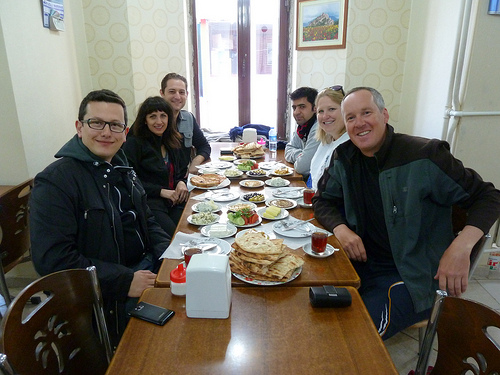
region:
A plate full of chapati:
[226, 219, 300, 283]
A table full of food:
[195, 123, 307, 302]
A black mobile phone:
[126, 301, 171, 326]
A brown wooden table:
[163, 329, 345, 368]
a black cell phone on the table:
[128, 300, 174, 327]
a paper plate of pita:
[229, 228, 301, 288]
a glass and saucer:
[301, 225, 336, 257]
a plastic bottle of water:
[268, 124, 279, 156]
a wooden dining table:
[125, 325, 393, 373]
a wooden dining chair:
[1, 263, 110, 370]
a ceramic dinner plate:
[272, 217, 314, 241]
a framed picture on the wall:
[295, 0, 350, 49]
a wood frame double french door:
[187, 1, 289, 138]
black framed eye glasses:
[80, 116, 130, 133]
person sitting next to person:
[25, 91, 176, 348]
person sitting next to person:
[309, 86, 496, 337]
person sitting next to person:
[122, 95, 194, 239]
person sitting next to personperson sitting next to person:
[159, 72, 210, 182]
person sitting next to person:
[279, 85, 331, 170]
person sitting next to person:
[310, 84, 351, 192]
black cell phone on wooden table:
[128, 301, 178, 333]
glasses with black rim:
[78, 114, 128, 135]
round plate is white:
[198, 222, 236, 239]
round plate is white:
[189, 201, 220, 215]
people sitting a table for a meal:
[4, 45, 498, 368]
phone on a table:
[129, 289, 181, 341]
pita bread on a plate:
[228, 222, 311, 301]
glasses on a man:
[81, 111, 129, 137]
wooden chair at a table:
[7, 258, 118, 368]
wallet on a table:
[306, 280, 353, 316]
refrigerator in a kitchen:
[412, 4, 498, 180]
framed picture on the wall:
[296, 1, 360, 48]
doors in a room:
[174, 2, 293, 137]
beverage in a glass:
[303, 223, 332, 263]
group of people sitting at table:
[29, 42, 425, 299]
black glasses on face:
[77, 106, 129, 133]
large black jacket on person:
[26, 150, 145, 287]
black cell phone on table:
[125, 295, 167, 328]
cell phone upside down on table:
[126, 296, 178, 328]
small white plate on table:
[300, 226, 335, 259]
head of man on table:
[335, 86, 394, 142]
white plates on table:
[172, 126, 302, 299]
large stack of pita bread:
[230, 229, 301, 286]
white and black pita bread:
[240, 240, 264, 261]